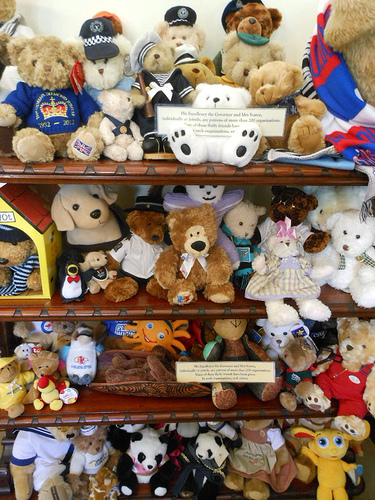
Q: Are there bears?
A: Yes, there is a bear.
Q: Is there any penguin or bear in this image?
A: Yes, there is a bear.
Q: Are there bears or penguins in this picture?
A: Yes, there is a bear.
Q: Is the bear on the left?
A: Yes, the bear is on the left of the image.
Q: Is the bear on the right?
A: No, the bear is on the left of the image.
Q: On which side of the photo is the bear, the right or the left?
A: The bear is on the left of the image.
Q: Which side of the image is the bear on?
A: The bear is on the left of the image.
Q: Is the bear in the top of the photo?
A: Yes, the bear is in the top of the image.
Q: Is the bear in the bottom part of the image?
A: No, the bear is in the top of the image.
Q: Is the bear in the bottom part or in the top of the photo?
A: The bear is in the top of the image.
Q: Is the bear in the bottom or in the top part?
A: The bear is in the top of the image.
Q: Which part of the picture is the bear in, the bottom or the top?
A: The bear is in the top of the image.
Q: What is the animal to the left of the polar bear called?
A: The animal is a bear.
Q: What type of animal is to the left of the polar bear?
A: The animal is a bear.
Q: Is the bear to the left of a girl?
A: No, the bear is to the left of the polar bear.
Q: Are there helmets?
A: No, there are no helmets.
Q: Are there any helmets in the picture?
A: No, there are no helmets.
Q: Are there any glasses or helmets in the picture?
A: No, there are no helmets or glasses.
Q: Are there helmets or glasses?
A: No, there are no helmets or glasses.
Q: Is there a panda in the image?
A: Yes, there are pandas.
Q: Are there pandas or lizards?
A: Yes, there are pandas.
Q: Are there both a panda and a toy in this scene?
A: Yes, there are both a panda and a toy.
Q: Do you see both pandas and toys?
A: Yes, there are both pandas and toys.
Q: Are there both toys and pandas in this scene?
A: Yes, there are both pandas and toys.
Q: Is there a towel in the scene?
A: No, there are no towels.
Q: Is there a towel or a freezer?
A: No, there are no towels or refrigerators.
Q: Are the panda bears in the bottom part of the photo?
A: Yes, the panda bears are in the bottom of the image.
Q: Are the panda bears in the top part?
A: No, the panda bears are in the bottom of the image.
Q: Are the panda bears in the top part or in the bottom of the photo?
A: The panda bears are in the bottom of the image.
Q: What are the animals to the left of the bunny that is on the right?
A: The animals are pandas.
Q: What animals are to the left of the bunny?
A: The animals are pandas.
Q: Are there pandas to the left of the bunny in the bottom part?
A: Yes, there are pandas to the left of the bunny.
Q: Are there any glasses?
A: No, there are no glasses.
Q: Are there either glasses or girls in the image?
A: No, there are no glasses or girls.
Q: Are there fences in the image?
A: No, there are no fences.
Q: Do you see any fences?
A: No, there are no fences.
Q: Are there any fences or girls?
A: No, there are no fences or girls.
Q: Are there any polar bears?
A: Yes, there is a polar bear.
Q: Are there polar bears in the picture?
A: Yes, there is a polar bear.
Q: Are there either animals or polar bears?
A: Yes, there is a polar bear.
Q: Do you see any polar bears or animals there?
A: Yes, there is a polar bear.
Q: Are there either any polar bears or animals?
A: Yes, there is a polar bear.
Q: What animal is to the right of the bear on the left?
A: The animal is a polar bear.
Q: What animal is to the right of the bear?
A: The animal is a polar bear.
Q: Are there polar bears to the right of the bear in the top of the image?
A: Yes, there is a polar bear to the right of the bear.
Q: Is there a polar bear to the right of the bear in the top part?
A: Yes, there is a polar bear to the right of the bear.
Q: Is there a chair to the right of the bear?
A: No, there is a polar bear to the right of the bear.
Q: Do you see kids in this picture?
A: No, there are no kids.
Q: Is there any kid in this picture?
A: No, there are no children.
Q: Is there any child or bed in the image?
A: No, there are no children or beds.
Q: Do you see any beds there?
A: No, there are no beds.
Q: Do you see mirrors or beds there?
A: No, there are no beds or mirrors.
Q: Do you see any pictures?
A: No, there are no pictures.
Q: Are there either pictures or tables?
A: No, there are no pictures or tables.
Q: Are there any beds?
A: No, there are no beds.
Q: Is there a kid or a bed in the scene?
A: No, there are no beds or children.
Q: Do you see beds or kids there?
A: No, there are no beds or kids.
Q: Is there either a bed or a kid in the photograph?
A: No, there are no beds or children.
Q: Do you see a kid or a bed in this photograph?
A: No, there are no beds or children.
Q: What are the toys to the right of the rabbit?
A: The toys are stuffed animals.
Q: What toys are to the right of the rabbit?
A: The toys are stuffed animals.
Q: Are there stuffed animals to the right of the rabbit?
A: Yes, there are stuffed animals to the right of the rabbit.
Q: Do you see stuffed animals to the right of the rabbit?
A: Yes, there are stuffed animals to the right of the rabbit.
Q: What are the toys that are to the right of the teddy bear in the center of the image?
A: The toys are stuffed animals.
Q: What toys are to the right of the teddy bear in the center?
A: The toys are stuffed animals.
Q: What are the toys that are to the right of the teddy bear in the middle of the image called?
A: The toys are stuffed animals.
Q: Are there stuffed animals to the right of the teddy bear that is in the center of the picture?
A: Yes, there are stuffed animals to the right of the teddy bear.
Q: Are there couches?
A: No, there are no couches.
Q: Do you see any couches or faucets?
A: No, there are no couches or faucets.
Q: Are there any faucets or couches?
A: No, there are no couches or faucets.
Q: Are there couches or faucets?
A: No, there are no couches or faucets.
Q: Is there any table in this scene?
A: No, there are no tables.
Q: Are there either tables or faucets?
A: No, there are no tables or faucets.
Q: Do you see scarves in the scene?
A: Yes, there is a scarf.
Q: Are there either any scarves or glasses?
A: Yes, there is a scarf.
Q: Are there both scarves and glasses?
A: No, there is a scarf but no glasses.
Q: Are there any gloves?
A: No, there are no gloves.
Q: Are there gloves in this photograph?
A: No, there are no gloves.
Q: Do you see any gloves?
A: No, there are no gloves.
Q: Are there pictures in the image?
A: No, there are no pictures.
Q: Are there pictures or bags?
A: No, there are no pictures or bags.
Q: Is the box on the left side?
A: Yes, the box is on the left of the image.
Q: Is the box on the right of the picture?
A: No, the box is on the left of the image.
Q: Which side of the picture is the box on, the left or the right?
A: The box is on the left of the image.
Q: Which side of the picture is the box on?
A: The box is on the left of the image.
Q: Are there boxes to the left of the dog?
A: Yes, there is a box to the left of the dog.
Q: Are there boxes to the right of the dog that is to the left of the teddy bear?
A: No, the box is to the left of the dog.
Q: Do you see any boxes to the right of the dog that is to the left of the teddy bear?
A: No, the box is to the left of the dog.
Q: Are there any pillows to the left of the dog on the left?
A: No, there is a box to the left of the dog.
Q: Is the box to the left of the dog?
A: Yes, the box is to the left of the dog.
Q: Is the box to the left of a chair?
A: No, the box is to the left of the dog.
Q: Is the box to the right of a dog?
A: No, the box is to the left of a dog.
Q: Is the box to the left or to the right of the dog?
A: The box is to the left of the dog.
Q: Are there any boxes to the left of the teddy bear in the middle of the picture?
A: Yes, there is a box to the left of the teddy bear.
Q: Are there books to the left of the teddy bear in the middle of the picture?
A: No, there is a box to the left of the teddy bear.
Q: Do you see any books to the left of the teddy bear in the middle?
A: No, there is a box to the left of the teddy bear.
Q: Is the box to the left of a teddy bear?
A: Yes, the box is to the left of a teddy bear.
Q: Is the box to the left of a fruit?
A: No, the box is to the left of a teddy bear.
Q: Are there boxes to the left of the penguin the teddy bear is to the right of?
A: Yes, there is a box to the left of the penguin.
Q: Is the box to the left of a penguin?
A: Yes, the box is to the left of a penguin.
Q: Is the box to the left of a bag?
A: No, the box is to the left of a penguin.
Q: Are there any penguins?
A: Yes, there is a penguin.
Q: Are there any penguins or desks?
A: Yes, there is a penguin.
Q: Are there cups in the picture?
A: No, there are no cups.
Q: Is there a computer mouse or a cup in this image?
A: No, there are no cups or computer mice.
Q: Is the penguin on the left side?
A: Yes, the penguin is on the left of the image.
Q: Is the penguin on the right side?
A: No, the penguin is on the left of the image.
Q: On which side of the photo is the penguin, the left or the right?
A: The penguin is on the left of the image.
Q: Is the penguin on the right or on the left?
A: The penguin is on the left of the image.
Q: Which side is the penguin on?
A: The penguin is on the left of the image.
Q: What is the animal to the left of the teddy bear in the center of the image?
A: The animal is a penguin.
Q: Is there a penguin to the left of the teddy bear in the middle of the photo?
A: Yes, there is a penguin to the left of the teddy bear.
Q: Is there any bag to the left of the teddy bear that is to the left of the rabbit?
A: No, there is a penguin to the left of the teddy bear.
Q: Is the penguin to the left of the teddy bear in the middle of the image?
A: Yes, the penguin is to the left of the teddy bear.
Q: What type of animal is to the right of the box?
A: The animal is a penguin.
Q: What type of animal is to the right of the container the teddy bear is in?
A: The animal is a penguin.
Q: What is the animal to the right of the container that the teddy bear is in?
A: The animal is a penguin.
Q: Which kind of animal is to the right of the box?
A: The animal is a penguin.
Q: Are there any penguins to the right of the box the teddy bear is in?
A: Yes, there is a penguin to the right of the box.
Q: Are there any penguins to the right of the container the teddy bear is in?
A: Yes, there is a penguin to the right of the box.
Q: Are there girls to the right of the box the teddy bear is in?
A: No, there is a penguin to the right of the box.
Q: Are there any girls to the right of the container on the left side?
A: No, there is a penguin to the right of the box.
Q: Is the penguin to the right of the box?
A: Yes, the penguin is to the right of the box.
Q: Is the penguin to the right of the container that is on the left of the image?
A: Yes, the penguin is to the right of the box.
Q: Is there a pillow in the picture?
A: No, there are no pillows.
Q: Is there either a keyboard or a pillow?
A: No, there are no pillows or keyboards.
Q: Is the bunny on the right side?
A: Yes, the bunny is on the right of the image.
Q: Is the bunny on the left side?
A: No, the bunny is on the right of the image.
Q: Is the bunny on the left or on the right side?
A: The bunny is on the right of the image.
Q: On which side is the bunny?
A: The bunny is on the right of the image.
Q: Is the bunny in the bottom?
A: Yes, the bunny is in the bottom of the image.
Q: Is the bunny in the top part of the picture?
A: No, the bunny is in the bottom of the image.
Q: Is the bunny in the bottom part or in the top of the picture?
A: The bunny is in the bottom of the image.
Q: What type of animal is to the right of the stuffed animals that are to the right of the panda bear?
A: The animal is a bunny.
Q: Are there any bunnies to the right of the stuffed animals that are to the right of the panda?
A: Yes, there is a bunny to the right of the stuffed animals.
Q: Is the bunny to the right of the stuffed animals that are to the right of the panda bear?
A: Yes, the bunny is to the right of the stuffed animals.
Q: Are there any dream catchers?
A: No, there are no dream catchers.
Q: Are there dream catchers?
A: No, there are no dream catchers.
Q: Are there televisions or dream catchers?
A: No, there are no dream catchers or televisions.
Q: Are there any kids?
A: No, there are no kids.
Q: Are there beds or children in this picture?
A: No, there are no children or beds.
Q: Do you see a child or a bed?
A: No, there are no children or beds.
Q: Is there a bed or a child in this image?
A: No, there are no children or beds.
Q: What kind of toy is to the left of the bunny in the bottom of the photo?
A: The toys are stuffed animals.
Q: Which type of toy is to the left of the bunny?
A: The toys are stuffed animals.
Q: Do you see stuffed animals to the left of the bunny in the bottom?
A: Yes, there are stuffed animals to the left of the bunny.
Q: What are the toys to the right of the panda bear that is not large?
A: The toys are stuffed animals.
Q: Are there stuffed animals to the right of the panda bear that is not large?
A: Yes, there are stuffed animals to the right of the panda.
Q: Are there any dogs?
A: Yes, there is a dog.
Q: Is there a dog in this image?
A: Yes, there is a dog.